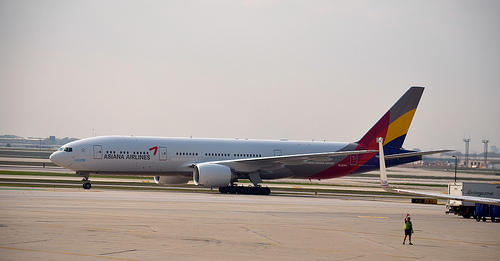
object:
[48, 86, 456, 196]
plane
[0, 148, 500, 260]
runway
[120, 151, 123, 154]
window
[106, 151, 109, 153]
window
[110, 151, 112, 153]
window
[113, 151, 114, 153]
window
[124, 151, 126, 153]
window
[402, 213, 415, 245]
man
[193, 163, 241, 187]
engine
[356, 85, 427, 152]
tail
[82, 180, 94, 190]
wheel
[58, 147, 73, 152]
windshield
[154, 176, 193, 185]
engine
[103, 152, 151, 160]
name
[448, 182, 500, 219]
truck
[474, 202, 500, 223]
cart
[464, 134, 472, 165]
tower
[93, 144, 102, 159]
door